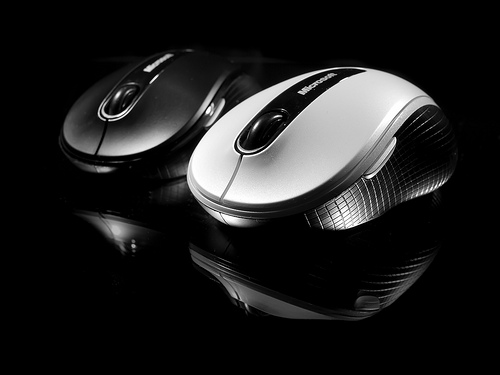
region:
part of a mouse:
[396, 172, 409, 182]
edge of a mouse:
[331, 197, 339, 205]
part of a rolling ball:
[258, 122, 269, 143]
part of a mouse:
[207, 141, 228, 188]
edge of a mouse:
[101, 130, 122, 138]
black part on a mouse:
[361, 164, 367, 176]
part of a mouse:
[218, 191, 239, 201]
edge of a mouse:
[175, 103, 184, 124]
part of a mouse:
[199, 143, 242, 219]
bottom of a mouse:
[273, 180, 277, 186]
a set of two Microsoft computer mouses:
[37, 18, 477, 248]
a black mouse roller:
[92, 71, 164, 129]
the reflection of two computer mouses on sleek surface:
[58, 175, 464, 344]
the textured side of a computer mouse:
[287, 105, 477, 255]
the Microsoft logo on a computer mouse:
[284, 56, 363, 105]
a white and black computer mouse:
[188, 39, 483, 252]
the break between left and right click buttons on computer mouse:
[214, 140, 270, 215]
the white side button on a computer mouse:
[356, 131, 415, 187]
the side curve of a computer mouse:
[247, 88, 445, 215]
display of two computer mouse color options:
[33, 26, 478, 245]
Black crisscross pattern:
[283, 90, 471, 262]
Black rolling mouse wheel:
[237, 98, 292, 152]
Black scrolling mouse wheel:
[99, 71, 152, 138]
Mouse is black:
[76, 45, 223, 165]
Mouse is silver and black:
[241, 69, 426, 222]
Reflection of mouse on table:
[93, 186, 407, 341]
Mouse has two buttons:
[183, 94, 328, 231]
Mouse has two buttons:
[59, 81, 225, 191]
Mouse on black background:
[16, 13, 493, 360]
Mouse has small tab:
[371, 130, 404, 205]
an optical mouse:
[107, 31, 387, 265]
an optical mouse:
[183, 48, 485, 347]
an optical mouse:
[199, 78, 367, 295]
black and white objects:
[48, 40, 469, 355]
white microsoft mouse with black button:
[209, 62, 481, 274]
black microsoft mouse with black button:
[37, 52, 255, 184]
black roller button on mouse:
[236, 107, 301, 160]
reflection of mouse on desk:
[188, 225, 448, 328]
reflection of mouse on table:
[68, 192, 175, 273]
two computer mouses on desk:
[28, 50, 465, 265]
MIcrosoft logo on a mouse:
[292, 62, 343, 107]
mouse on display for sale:
[54, 32, 456, 278]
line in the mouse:
[209, 150, 261, 225]